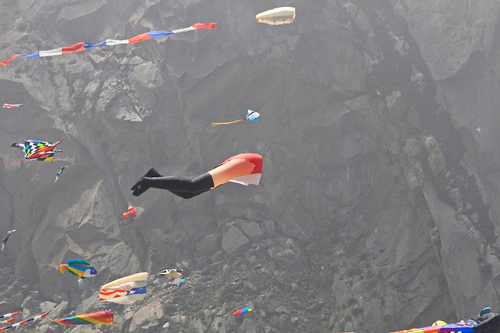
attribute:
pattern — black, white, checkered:
[11, 135, 66, 162]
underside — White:
[227, 169, 264, 191]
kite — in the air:
[146, 249, 196, 295]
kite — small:
[3, 101, 42, 120]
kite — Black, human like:
[129, 152, 261, 200]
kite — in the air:
[56, 258, 101, 278]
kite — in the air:
[47, 308, 115, 331]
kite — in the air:
[237, 103, 267, 129]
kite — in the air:
[10, 132, 66, 168]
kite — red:
[132, 143, 277, 207]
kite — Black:
[134, 13, 286, 60]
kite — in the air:
[116, 197, 148, 222]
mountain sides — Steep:
[29, 185, 118, 330]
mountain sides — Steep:
[421, 7, 498, 197]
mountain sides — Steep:
[106, 3, 420, 330]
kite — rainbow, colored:
[52, 313, 119, 325]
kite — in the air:
[131, 151, 287, 196]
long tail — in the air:
[7, 16, 242, 63]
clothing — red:
[223, 145, 268, 187]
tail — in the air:
[162, 17, 218, 82]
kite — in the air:
[126, 143, 273, 204]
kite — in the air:
[8, 125, 99, 200]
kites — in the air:
[116, 153, 273, 195]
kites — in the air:
[36, 30, 259, 312]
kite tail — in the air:
[204, 114, 244, 126]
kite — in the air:
[46, 309, 113, 327]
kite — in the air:
[38, 234, 173, 308]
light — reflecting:
[143, 172, 209, 183]